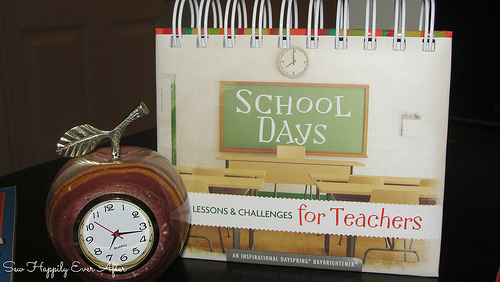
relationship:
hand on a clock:
[112, 230, 150, 248] [23, 145, 198, 278]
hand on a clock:
[108, 228, 120, 251] [23, 145, 198, 278]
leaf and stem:
[56, 117, 106, 161] [106, 105, 149, 159]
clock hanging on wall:
[264, 40, 331, 97] [159, 45, 442, 172]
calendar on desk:
[153, 0, 454, 278] [6, 126, 496, 280]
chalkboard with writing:
[217, 79, 367, 159] [236, 89, 351, 146]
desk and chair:
[220, 153, 363, 190] [275, 140, 309, 180]